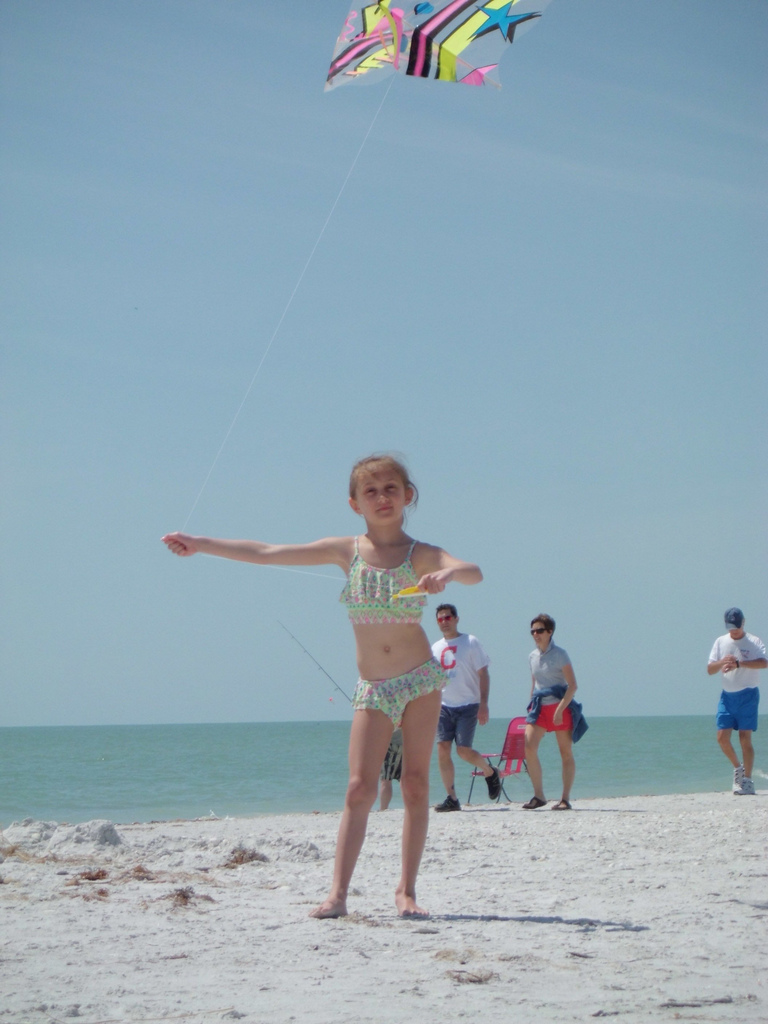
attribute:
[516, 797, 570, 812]
sandals — black 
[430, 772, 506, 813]
shoes — black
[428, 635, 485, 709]
shirt — white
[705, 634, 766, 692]
shirt — white 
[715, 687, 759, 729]
shorts — blue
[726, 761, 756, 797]
shoes — white 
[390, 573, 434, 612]
holder — yellow  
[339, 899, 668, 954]
shadow — gils 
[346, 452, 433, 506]
hair — blonde 